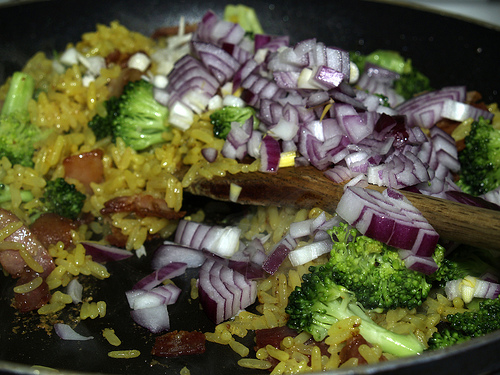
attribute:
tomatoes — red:
[34, 141, 236, 223]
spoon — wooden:
[193, 129, 437, 260]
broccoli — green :
[101, 80, 185, 158]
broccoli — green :
[96, 69, 176, 161]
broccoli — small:
[111, 79, 192, 153]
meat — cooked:
[102, 187, 166, 222]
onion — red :
[192, 254, 259, 331]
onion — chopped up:
[109, 207, 297, 334]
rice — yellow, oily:
[55, 41, 349, 311]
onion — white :
[435, 97, 492, 128]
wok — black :
[368, 3, 490, 83]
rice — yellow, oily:
[0, 29, 255, 305]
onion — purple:
[194, 260, 269, 316]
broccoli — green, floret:
[308, 257, 430, 355]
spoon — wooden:
[187, 145, 499, 263]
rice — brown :
[79, 26, 154, 56]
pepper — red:
[56, 145, 106, 187]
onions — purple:
[53, 10, 498, 328]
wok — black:
[7, 2, 499, 372]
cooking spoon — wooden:
[195, 162, 499, 249]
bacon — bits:
[59, 148, 106, 184]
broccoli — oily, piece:
[91, 78, 174, 151]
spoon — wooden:
[187, 164, 497, 253]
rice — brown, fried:
[3, 22, 463, 373]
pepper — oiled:
[3, 214, 49, 271]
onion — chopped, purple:
[344, 186, 445, 245]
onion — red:
[157, 24, 461, 250]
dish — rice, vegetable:
[2, 5, 484, 369]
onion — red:
[198, 256, 257, 323]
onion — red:
[286, 237, 331, 266]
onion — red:
[173, 215, 240, 256]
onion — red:
[334, 184, 392, 240]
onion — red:
[341, 109, 371, 144]